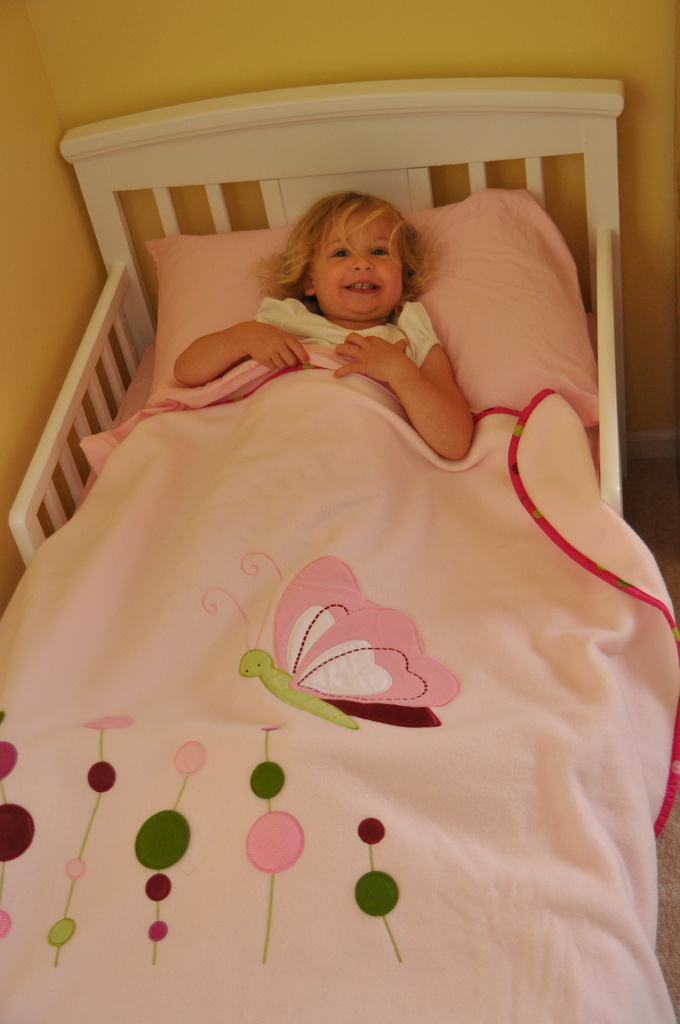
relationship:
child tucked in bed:
[169, 189, 476, 465] [4, 74, 629, 578]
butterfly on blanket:
[193, 541, 469, 748] [4, 364, 658, 1020]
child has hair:
[171, 189, 474, 465] [263, 182, 429, 279]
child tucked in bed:
[171, 189, 474, 465] [9, 285, 622, 1021]